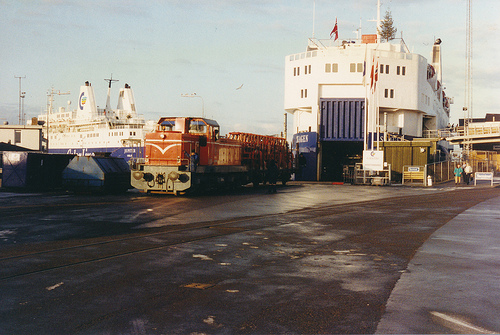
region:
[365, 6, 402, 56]
tree on a building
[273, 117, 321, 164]
blue and silver sign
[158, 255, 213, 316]
yellow painted line on road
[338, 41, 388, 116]
three flags on poles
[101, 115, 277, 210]
red and white train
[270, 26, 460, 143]
large white building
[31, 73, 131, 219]
white and blue ship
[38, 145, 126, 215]
two blue dumpsters on road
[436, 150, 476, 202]
people standing in driveway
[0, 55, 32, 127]
tall wooden electric pole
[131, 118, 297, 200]
Train that is converted.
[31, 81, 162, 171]
Large white ship in background.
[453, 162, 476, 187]
People on the street.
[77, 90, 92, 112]
Name of the ship.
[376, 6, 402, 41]
Tree on top of ship.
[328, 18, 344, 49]
Flag on top of the ship.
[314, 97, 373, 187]
Garage door on the ship.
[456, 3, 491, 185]
Tower in the harbor.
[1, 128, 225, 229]
Shadows from the ships.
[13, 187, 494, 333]
Blacktop in the parking area.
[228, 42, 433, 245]
the ship is rusty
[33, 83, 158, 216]
the ship is rusty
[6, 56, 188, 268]
the ship is rusty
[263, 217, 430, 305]
The pavement looks wet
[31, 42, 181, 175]
The boat is blue and white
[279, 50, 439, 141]
The building has windows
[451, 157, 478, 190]
People are walking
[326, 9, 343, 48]
The flag is flying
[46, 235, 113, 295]
The pavement is dark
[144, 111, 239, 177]
The man is standing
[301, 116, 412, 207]
The door is open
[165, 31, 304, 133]
The sky is cloudy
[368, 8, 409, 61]
There is a tree on the roof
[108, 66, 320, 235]
a train on tracks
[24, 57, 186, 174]
a boat in the water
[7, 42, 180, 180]
a boat in the distance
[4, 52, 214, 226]
a carnival boat in the distance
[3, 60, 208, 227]
a cruise boat in the distance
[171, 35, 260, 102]
birds flying in the air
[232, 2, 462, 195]
a white building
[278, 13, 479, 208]
a white with blue door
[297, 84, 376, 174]
a blue metal door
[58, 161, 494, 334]
a cemented area